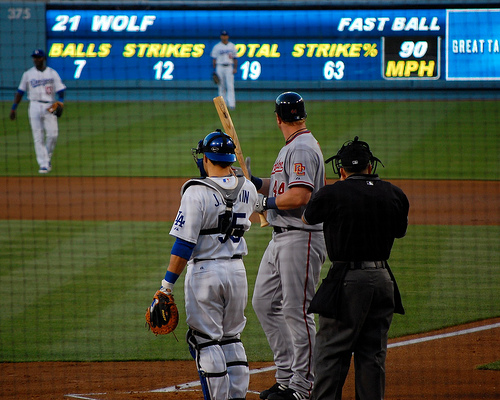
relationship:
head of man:
[205, 11, 267, 113] [213, 26, 235, 51]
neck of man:
[213, 46, 243, 49] [213, 26, 235, 51]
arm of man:
[200, 44, 230, 85] [213, 26, 235, 51]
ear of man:
[220, 27, 226, 37] [213, 26, 235, 51]